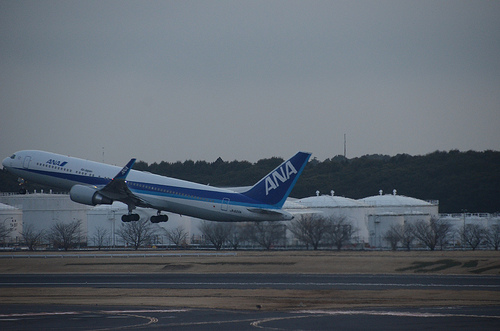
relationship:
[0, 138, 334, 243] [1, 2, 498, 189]
airplane in air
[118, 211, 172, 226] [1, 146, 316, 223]
wheels on airplane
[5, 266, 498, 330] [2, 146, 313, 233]
runway beneath airplane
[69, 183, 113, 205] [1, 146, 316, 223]
engine on airplane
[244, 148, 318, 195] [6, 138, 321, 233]
ana logo on airplane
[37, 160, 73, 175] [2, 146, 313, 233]
windows on airplane